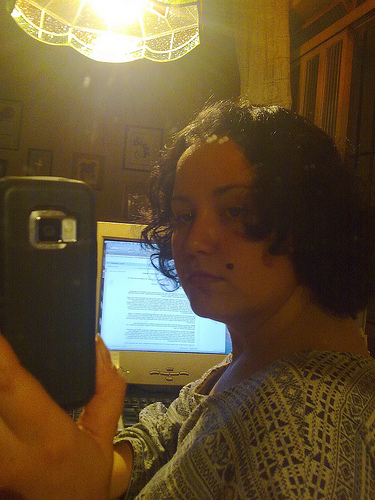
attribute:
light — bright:
[2, 1, 209, 69]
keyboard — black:
[120, 387, 191, 428]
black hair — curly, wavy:
[139, 93, 374, 319]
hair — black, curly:
[125, 93, 374, 321]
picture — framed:
[121, 120, 165, 178]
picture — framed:
[71, 149, 107, 188]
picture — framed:
[21, 143, 56, 178]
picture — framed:
[1, 93, 27, 159]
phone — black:
[0, 173, 100, 413]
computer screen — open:
[66, 219, 227, 354]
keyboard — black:
[120, 395, 186, 422]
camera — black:
[4, 179, 98, 403]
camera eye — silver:
[31, 214, 73, 244]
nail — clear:
[83, 314, 122, 370]